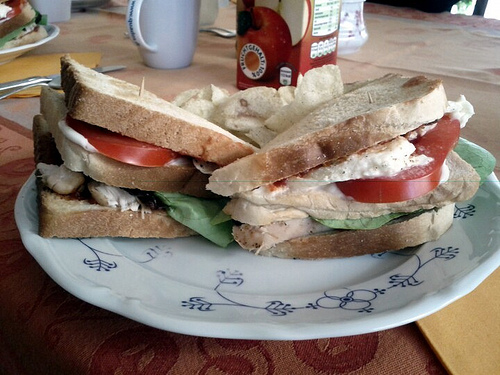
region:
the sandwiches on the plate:
[33, 33, 454, 273]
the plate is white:
[20, 57, 495, 343]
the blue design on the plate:
[190, 260, 450, 310]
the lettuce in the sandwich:
[70, 125, 177, 166]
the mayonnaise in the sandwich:
[321, 150, 412, 170]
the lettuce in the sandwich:
[165, 192, 226, 239]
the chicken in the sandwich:
[235, 200, 345, 235]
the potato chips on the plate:
[166, 61, 346, 136]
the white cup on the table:
[123, 2, 200, 69]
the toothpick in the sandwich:
[120, 70, 156, 100]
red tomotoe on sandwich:
[98, 113, 190, 180]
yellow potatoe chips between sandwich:
[224, 69, 322, 121]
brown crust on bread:
[101, 84, 196, 158]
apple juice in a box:
[241, 3, 348, 87]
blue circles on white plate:
[297, 266, 372, 326]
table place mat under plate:
[65, 323, 162, 374]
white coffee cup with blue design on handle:
[111, 0, 228, 82]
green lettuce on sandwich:
[168, 193, 228, 243]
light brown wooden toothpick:
[130, 72, 168, 110]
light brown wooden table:
[443, 309, 498, 359]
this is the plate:
[145, 260, 413, 332]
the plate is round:
[84, 252, 485, 343]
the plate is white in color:
[262, 265, 310, 280]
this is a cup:
[126, 0, 206, 71]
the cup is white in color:
[153, 8, 180, 59]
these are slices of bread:
[26, 54, 469, 248]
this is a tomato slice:
[371, 178, 418, 193]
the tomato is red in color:
[378, 180, 413, 195]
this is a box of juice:
[240, 7, 336, 59]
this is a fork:
[1, 79, 34, 88]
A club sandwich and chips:
[28, 12, 495, 340]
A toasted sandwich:
[35, 56, 476, 255]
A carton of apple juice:
[231, 2, 342, 92]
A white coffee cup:
[128, 3, 210, 73]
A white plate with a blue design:
[18, 127, 498, 347]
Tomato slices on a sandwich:
[61, 103, 461, 192]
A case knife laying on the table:
[5, 58, 129, 104]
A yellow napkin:
[0, 47, 112, 90]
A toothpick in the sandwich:
[135, 78, 161, 142]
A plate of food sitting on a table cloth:
[2, 53, 499, 373]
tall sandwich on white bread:
[13, 36, 491, 260]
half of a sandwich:
[15, 36, 251, 256]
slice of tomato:
[64, 118, 179, 176]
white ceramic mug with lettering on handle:
[118, 0, 213, 77]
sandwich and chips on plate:
[16, 25, 495, 339]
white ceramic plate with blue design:
[7, 164, 495, 339]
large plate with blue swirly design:
[11, 161, 496, 346]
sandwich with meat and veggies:
[22, 47, 493, 258]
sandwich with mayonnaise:
[18, 48, 481, 276]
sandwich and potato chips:
[15, 41, 499, 271]